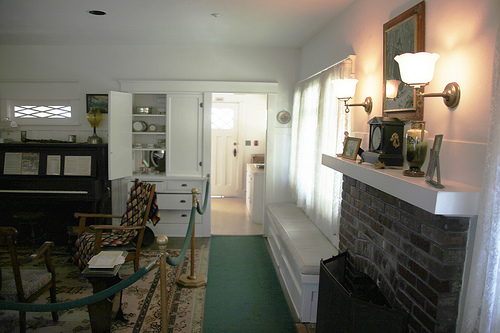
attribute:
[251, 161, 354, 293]
cushion — white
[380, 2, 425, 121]
picture frame — large, brown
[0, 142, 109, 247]
piano — large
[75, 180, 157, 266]
rocking chair — brown, rocker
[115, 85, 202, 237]
cabinet — white 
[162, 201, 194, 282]
rope — long, green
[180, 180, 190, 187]
handle — black 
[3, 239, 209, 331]
rug — large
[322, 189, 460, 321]
fireplace — bricked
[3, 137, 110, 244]
piano — brown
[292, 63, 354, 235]
curtains — white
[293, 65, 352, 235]
window — large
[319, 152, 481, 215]
mantle — white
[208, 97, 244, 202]
door — white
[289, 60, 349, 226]
curtains — white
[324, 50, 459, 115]
lights — white, bronze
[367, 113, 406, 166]
clock — old, brown, white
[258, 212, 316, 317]
chest — white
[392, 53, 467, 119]
lamp — wall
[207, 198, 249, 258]
floor — white 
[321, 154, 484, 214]
fireplace mantle — white